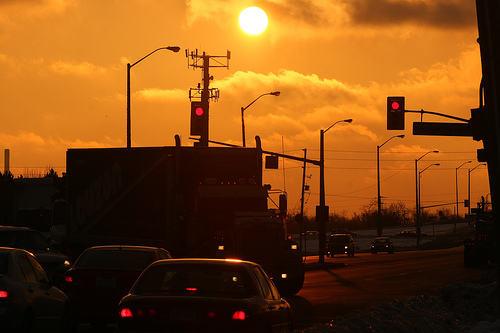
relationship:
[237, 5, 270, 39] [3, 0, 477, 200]
sun in sky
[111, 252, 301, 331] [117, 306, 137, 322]
car with brake light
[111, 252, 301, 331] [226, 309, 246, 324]
car with brake light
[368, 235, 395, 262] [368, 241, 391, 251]
car driving with its lights on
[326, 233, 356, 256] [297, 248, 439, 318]
cars driving on road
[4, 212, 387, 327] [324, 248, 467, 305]
cars on road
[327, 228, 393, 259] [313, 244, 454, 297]
cars on street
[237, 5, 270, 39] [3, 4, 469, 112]
sun in sky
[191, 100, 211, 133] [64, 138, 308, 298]
traffic light above truck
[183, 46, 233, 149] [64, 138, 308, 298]
tower above truck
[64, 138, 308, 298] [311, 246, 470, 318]
truck on road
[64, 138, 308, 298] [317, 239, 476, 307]
truck on street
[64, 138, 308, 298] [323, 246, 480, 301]
truck on road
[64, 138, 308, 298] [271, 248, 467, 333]
truck on road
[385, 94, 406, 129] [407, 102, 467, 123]
traffic light on pole